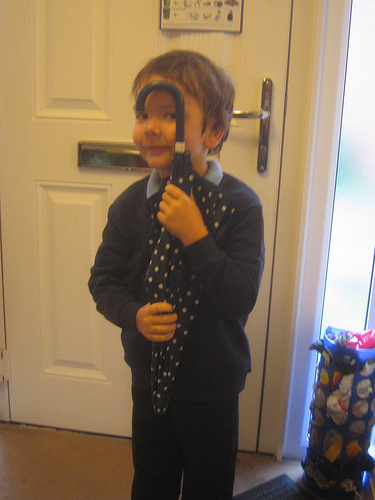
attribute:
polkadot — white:
[144, 274, 152, 285]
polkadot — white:
[155, 280, 163, 290]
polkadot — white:
[163, 241, 172, 251]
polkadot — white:
[170, 245, 178, 255]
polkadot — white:
[152, 264, 158, 273]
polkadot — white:
[166, 274, 170, 278]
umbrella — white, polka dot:
[121, 81, 240, 424]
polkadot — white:
[179, 303, 188, 316]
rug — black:
[230, 470, 310, 497]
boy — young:
[88, 47, 267, 499]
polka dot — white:
[172, 359, 186, 371]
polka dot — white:
[170, 336, 184, 347]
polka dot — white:
[186, 284, 193, 303]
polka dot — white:
[146, 269, 156, 283]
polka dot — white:
[162, 240, 172, 259]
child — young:
[88, 49, 287, 496]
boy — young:
[85, 40, 287, 496]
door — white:
[0, 0, 302, 458]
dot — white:
[156, 252, 167, 266]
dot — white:
[164, 238, 172, 255]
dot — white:
[146, 274, 156, 289]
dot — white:
[152, 289, 163, 303]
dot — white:
[154, 277, 167, 292]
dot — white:
[178, 302, 190, 316]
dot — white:
[161, 268, 171, 280]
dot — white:
[154, 251, 167, 261]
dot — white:
[156, 251, 165, 261]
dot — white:
[178, 302, 188, 315]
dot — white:
[179, 303, 188, 315]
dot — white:
[171, 359, 181, 367]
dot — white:
[152, 374, 164, 387]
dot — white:
[209, 217, 222, 229]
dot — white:
[169, 243, 179, 256]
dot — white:
[154, 280, 164, 290]